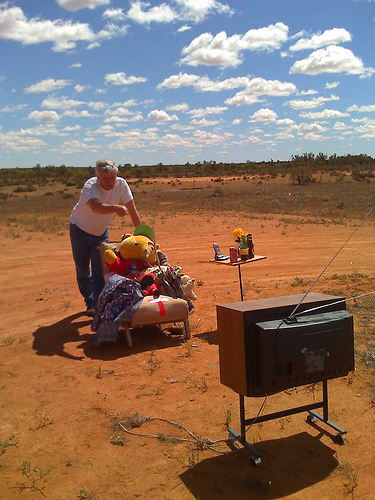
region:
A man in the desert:
[2, 154, 370, 495]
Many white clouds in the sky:
[1, 0, 372, 160]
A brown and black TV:
[209, 282, 360, 466]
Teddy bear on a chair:
[98, 222, 197, 346]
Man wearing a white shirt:
[63, 159, 138, 239]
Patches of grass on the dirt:
[292, 263, 373, 409]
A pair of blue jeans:
[64, 218, 113, 305]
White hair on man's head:
[86, 155, 125, 191]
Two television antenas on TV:
[287, 200, 372, 317]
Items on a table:
[206, 223, 274, 300]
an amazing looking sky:
[9, 2, 364, 148]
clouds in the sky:
[0, 10, 368, 141]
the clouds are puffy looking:
[0, 0, 369, 151]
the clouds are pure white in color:
[4, 5, 368, 146]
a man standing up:
[70, 166, 138, 313]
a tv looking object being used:
[211, 287, 343, 402]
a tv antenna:
[289, 190, 374, 326]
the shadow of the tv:
[159, 423, 338, 498]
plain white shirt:
[65, 180, 137, 232]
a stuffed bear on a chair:
[104, 233, 165, 294]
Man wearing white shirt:
[69, 162, 144, 315]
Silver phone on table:
[205, 239, 227, 263]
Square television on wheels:
[202, 290, 364, 465]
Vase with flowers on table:
[229, 226, 245, 258]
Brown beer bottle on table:
[244, 231, 256, 257]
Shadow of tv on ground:
[177, 426, 343, 498]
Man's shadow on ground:
[30, 308, 94, 358]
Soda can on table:
[225, 245, 238, 264]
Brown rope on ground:
[109, 401, 244, 466]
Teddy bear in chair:
[104, 228, 164, 294]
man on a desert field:
[66, 158, 142, 317]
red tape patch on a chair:
[147, 294, 170, 318]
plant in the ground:
[11, 457, 56, 495]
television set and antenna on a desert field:
[213, 207, 372, 466]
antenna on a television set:
[277, 206, 373, 325]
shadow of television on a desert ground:
[175, 428, 340, 498]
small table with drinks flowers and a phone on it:
[205, 225, 267, 299]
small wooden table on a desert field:
[207, 225, 268, 302]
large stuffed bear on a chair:
[102, 223, 165, 281]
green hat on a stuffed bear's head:
[131, 222, 155, 239]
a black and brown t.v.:
[217, 290, 359, 395]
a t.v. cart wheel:
[248, 456, 266, 468]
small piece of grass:
[330, 452, 362, 486]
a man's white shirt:
[64, 174, 134, 238]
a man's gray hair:
[93, 158, 124, 175]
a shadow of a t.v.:
[175, 430, 337, 499]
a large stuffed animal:
[99, 233, 156, 275]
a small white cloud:
[103, 71, 150, 87]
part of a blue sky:
[121, 40, 167, 67]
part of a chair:
[97, 240, 194, 343]